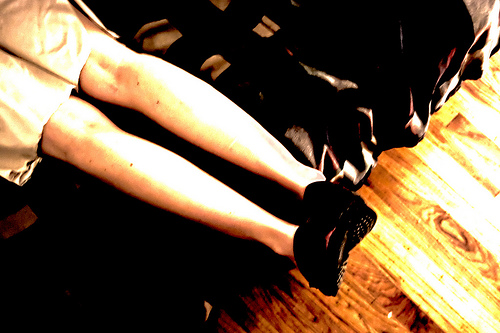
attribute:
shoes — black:
[293, 181, 377, 297]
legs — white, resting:
[47, 18, 323, 260]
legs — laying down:
[43, 29, 377, 295]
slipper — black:
[295, 227, 347, 296]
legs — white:
[4, 3, 382, 308]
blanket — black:
[2, 2, 490, 331]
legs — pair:
[47, 42, 327, 271]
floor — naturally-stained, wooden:
[396, 172, 459, 276]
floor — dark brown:
[296, 271, 433, 331]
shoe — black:
[294, 222, 349, 295]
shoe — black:
[299, 179, 377, 249]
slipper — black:
[278, 183, 376, 239]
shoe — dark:
[295, 179, 377, 238]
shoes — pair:
[301, 159, 386, 326]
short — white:
[0, 1, 117, 188]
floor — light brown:
[221, 48, 499, 331]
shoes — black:
[284, 217, 364, 302]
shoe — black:
[307, 170, 383, 256]